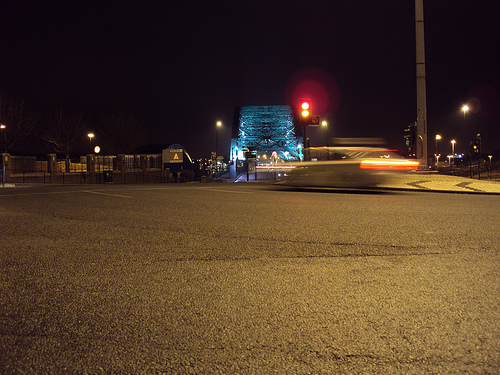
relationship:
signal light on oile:
[298, 97, 311, 121] [300, 117, 307, 158]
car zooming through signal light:
[272, 132, 425, 197] [292, 84, 319, 168]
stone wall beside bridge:
[226, 108, 311, 205] [240, 101, 315, 193]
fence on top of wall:
[1, 152, 163, 174] [0, 171, 164, 188]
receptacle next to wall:
[95, 160, 113, 182] [0, 158, 191, 186]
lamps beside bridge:
[1, 83, 488, 184] [278, 132, 496, 193]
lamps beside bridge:
[458, 100, 474, 121] [278, 132, 496, 193]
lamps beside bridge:
[446, 136, 457, 146] [278, 132, 496, 193]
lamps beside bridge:
[435, 130, 447, 140] [278, 132, 496, 193]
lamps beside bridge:
[316, 115, 336, 132] [278, 132, 496, 193]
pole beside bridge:
[401, 1, 443, 173] [278, 132, 496, 193]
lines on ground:
[74, 165, 266, 199] [39, 145, 426, 373]